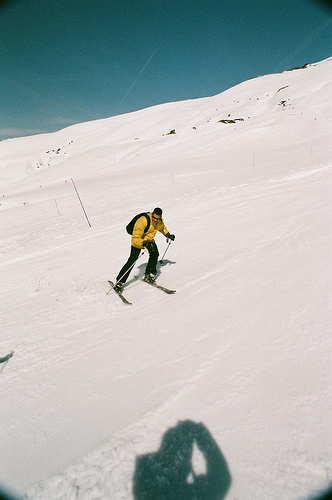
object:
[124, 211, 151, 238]
backpack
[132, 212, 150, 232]
back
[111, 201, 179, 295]
skier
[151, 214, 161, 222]
sunglasses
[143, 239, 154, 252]
right glove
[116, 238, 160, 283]
pants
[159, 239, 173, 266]
ski pole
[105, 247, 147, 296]
ski pole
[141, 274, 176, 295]
left ski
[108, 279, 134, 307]
right ski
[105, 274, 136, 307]
skis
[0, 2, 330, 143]
sky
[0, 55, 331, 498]
slope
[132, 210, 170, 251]
ski jacket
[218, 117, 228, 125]
rock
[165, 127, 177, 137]
rock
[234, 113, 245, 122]
rock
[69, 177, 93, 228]
pole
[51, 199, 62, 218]
pole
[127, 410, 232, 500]
shadow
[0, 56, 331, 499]
snow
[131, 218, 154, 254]
arm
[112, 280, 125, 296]
foot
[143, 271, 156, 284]
foot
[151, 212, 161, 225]
face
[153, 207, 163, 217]
hair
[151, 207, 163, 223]
head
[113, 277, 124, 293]
boot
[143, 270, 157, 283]
boot